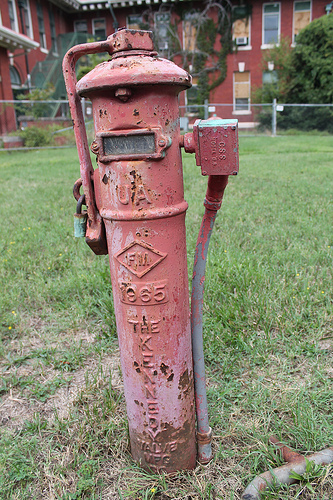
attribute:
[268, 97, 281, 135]
post — grey metal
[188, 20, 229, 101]
vines — green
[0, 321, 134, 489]
dirt — brown , sparse patches 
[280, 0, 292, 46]
wall — red brick 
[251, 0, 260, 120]
wall — red brick 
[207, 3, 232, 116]
wall — red brick 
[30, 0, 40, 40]
wall — red brick 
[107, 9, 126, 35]
wall — red brick 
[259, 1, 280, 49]
trim — white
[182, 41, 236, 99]
vines — green 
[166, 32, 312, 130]
wall — building 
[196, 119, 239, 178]
box — electric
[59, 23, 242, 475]
utility box — stamped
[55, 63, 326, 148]
fence — chainlink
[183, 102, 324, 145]
fence — grey, metal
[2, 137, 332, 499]
grass — Green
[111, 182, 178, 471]
lettering — raised, metal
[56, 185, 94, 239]
lock — rusted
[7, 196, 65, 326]
flowers — yellow